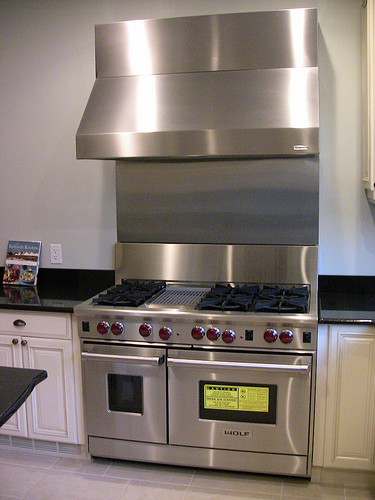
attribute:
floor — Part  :
[3, 445, 80, 495]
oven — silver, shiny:
[82, 340, 315, 484]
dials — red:
[83, 312, 307, 348]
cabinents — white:
[2, 312, 80, 454]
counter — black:
[0, 283, 373, 324]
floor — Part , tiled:
[4, 446, 375, 499]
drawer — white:
[2, 310, 75, 338]